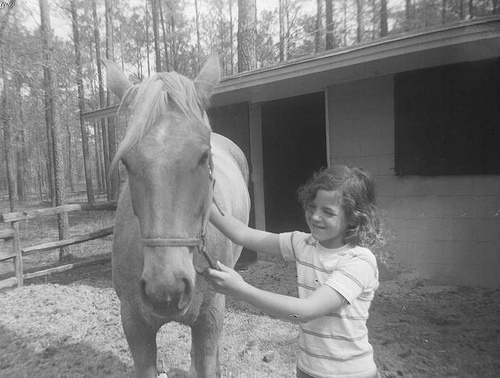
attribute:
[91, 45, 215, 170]
mane — long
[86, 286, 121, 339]
imprints — small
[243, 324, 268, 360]
imprints — small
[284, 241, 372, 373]
shirt — striped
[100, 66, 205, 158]
hair — long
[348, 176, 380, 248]
hair — brown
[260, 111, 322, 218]
door — open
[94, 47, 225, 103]
ears — up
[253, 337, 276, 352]
imprint — small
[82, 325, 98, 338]
imprint — small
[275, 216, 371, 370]
shirt — striped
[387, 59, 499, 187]
board — dark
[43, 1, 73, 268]
trunk — narrow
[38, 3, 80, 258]
trees — tall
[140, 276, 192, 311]
snout — black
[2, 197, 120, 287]
fence — wooden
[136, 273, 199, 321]
horse's nose — dark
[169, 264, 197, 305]
nostril — black, large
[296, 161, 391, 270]
hair — long, curly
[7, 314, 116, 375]
imprints — small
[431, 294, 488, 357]
imprints — small